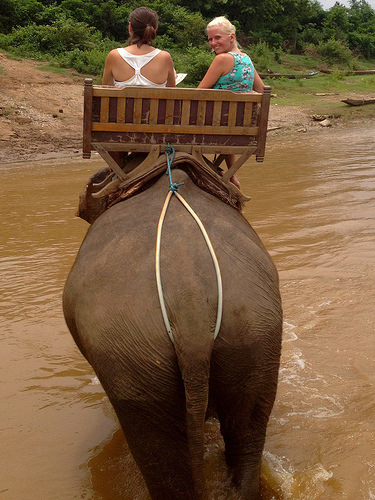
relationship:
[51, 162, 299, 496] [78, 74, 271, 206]
elephant attached to bench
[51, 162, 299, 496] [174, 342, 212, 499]
elephant has tail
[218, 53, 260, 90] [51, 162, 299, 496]
back of an elephant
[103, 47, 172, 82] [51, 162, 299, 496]
back of an elephant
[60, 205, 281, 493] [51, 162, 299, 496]
back of an elephant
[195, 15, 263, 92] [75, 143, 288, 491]
person riding elephant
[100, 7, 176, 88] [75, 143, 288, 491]
person riding elephant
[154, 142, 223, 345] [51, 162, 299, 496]
cord attached to elephant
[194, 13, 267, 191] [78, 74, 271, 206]
woman on bench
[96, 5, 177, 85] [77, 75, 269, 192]
woman on a bench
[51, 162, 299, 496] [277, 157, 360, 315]
elephant walking in water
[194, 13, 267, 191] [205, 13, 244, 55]
woman has hair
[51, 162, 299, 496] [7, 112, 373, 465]
elephant in water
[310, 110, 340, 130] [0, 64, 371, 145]
rocks on ground